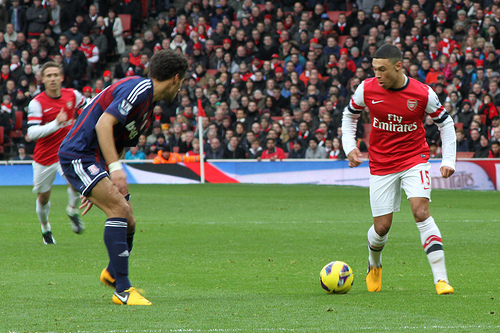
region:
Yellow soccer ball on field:
[318, 256, 353, 294]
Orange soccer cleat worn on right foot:
[363, 258, 383, 293]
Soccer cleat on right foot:
[364, 263, 384, 291]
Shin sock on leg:
[415, 216, 448, 278]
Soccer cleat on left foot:
[434, 278, 453, 294]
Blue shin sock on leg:
[103, 218, 132, 292]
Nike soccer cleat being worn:
[112, 288, 151, 305]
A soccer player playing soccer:
[342, 44, 457, 294]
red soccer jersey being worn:
[342, 75, 449, 175]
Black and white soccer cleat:
[40, 229, 56, 245]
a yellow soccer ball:
[318, 259, 355, 296]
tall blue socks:
[101, 214, 132, 293]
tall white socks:
[363, 214, 450, 282]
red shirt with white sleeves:
[338, 75, 458, 175]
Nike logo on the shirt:
[371, 98, 383, 104]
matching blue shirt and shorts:
[56, 74, 158, 198]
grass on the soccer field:
[0, 182, 498, 332]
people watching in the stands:
[1, 1, 499, 165]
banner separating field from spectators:
[1, 159, 498, 190]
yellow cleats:
[98, 268, 153, 306]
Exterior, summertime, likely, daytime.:
[2, 0, 497, 325]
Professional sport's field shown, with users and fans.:
[0, 0, 495, 326]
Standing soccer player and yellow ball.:
[326, 38, 471, 301]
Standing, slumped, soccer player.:
[75, 57, 190, 327]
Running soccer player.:
[25, 52, 91, 245]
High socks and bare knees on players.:
[26, 187, 472, 307]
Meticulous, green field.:
[186, 205, 247, 291]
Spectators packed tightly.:
[220, 10, 320, 156]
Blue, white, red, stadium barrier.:
[163, 156, 298, 182]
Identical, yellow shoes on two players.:
[97, 263, 463, 304]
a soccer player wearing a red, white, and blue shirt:
[343, 39, 470, 301]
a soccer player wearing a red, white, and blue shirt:
[28, 59, 94, 247]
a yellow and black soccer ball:
[312, 254, 359, 298]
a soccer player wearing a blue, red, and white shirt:
[59, 52, 196, 309]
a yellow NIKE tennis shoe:
[107, 283, 154, 308]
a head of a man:
[364, 42, 409, 91]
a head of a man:
[145, 44, 191, 101]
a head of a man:
[37, 58, 67, 93]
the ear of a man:
[391, 55, 406, 74]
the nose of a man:
[371, 68, 386, 82]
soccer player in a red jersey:
[331, 42, 468, 301]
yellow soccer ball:
[314, 257, 363, 302]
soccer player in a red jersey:
[24, 57, 86, 246]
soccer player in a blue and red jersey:
[57, 29, 194, 309]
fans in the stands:
[7, 2, 496, 162]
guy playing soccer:
[308, 33, 465, 302]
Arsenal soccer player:
[338, 38, 456, 298]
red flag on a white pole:
[193, 97, 210, 183]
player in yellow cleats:
[57, 41, 191, 309]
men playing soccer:
[25, 44, 464, 305]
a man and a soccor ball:
[309, 30, 459, 303]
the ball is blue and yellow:
[316, 255, 359, 299]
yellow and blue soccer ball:
[320, 256, 356, 294]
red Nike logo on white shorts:
[422, 185, 429, 192]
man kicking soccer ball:
[313, 44, 458, 301]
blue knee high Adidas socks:
[102, 215, 134, 286]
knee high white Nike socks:
[416, 216, 451, 281]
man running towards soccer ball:
[29, 60, 71, 244]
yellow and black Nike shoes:
[113, 287, 149, 304]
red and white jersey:
[346, 78, 448, 170]